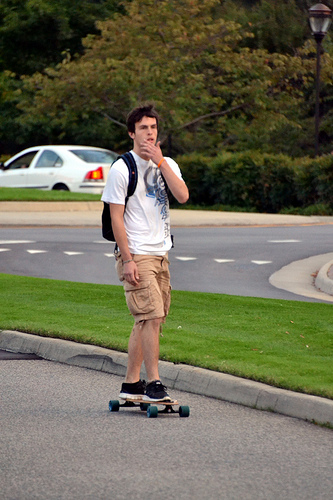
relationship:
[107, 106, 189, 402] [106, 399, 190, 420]
boy riding skateboard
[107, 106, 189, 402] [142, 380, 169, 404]
boy wearing tennis shoes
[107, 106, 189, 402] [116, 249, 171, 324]
boy in shorts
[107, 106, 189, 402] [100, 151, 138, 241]
boy carrying backpack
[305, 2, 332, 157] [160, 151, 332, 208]
lamp post standing near hedge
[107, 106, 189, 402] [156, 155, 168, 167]
boy wearing band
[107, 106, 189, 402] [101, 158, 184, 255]
boy dressed in t-shirt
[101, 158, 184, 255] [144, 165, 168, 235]
t-shirt has design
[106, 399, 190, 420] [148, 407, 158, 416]
skateboard has wheels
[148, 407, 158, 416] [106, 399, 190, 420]
wheels on skateboard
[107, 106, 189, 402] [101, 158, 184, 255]
boy has t-shirt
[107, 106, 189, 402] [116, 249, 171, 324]
boy has shorts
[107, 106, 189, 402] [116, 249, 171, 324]
boy with shorts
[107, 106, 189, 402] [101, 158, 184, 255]
boy wearing t-shirt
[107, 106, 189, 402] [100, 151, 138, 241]
boy wearing backpack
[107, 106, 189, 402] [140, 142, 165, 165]
boy with hand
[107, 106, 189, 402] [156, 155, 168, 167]
boy has band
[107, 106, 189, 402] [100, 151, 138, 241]
boy has backpack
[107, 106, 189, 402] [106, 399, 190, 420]
boy on skateboard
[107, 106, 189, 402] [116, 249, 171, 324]
boy wearing shorts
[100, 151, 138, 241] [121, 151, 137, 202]
backpack has strap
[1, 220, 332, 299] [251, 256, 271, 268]
road has triangles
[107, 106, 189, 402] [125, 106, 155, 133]
boy has hair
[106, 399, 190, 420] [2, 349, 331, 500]
skateboard on road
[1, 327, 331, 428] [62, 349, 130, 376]
curb has mark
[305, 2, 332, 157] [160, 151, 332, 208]
lamp post behind hedge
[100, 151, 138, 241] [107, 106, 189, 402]
backpack on boy